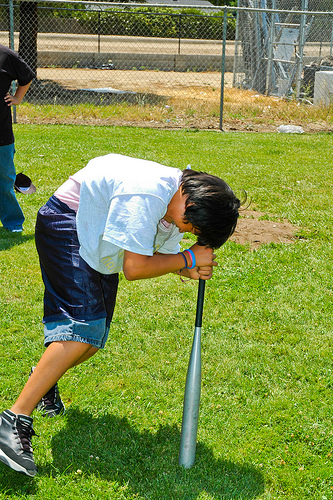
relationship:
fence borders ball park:
[0, 0, 332, 132] [1, 122, 332, 498]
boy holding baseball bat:
[1, 149, 246, 475] [177, 278, 205, 470]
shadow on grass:
[0, 405, 264, 497] [1, 121, 332, 498]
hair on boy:
[163, 167, 253, 261] [1, 149, 246, 475]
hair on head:
[163, 167, 253, 261] [164, 167, 243, 249]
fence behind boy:
[0, 0, 332, 132] [1, 149, 246, 475]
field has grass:
[9, 125, 322, 491] [1, 121, 332, 498]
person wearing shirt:
[0, 41, 39, 234] [2, 37, 29, 150]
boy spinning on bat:
[0, 153, 251, 479] [172, 267, 239, 482]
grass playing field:
[1, 121, 332, 498] [86, 303, 293, 492]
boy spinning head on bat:
[1, 149, 246, 475] [180, 297, 212, 480]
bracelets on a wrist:
[176, 245, 197, 275] [157, 245, 199, 274]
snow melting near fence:
[273, 119, 311, 140] [229, 47, 315, 112]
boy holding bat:
[0, 153, 251, 479] [168, 277, 216, 462]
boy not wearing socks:
[0, 153, 251, 479] [5, 400, 29, 438]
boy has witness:
[0, 153, 251, 479] [15, 70, 38, 129]